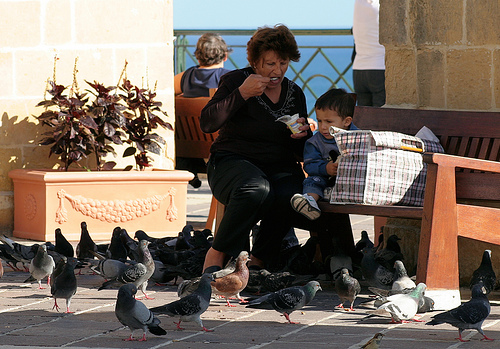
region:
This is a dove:
[425, 276, 493, 345]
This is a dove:
[366, 279, 442, 329]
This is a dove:
[205, 242, 260, 299]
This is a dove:
[235, 275, 331, 332]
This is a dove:
[325, 263, 376, 322]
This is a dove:
[156, 270, 242, 325]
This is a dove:
[110, 282, 184, 347]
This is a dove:
[40, 253, 120, 323]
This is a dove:
[96, 237, 177, 302]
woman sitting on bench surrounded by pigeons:
[17, 10, 495, 340]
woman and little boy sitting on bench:
[200, 21, 495, 296]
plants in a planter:
[15, 55, 192, 235]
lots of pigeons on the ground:
[1, 215, 486, 336]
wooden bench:
[207, 76, 492, 288]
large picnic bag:
[327, 125, 472, 202]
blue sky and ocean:
[165, 2, 352, 129]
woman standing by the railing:
[355, 0, 397, 101]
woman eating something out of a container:
[200, 28, 300, 268]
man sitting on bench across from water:
[175, 28, 247, 163]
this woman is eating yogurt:
[211, 6, 336, 251]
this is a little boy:
[277, 67, 387, 239]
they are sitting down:
[200, 16, 485, 286]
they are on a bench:
[203, 21, 458, 269]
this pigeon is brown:
[200, 239, 272, 301]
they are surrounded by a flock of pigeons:
[0, 209, 498, 343]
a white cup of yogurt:
[268, 97, 318, 167]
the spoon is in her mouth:
[258, 67, 295, 95]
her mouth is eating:
[242, 18, 312, 108]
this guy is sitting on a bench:
[172, 18, 228, 143]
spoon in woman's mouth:
[262, 75, 277, 81]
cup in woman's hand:
[279, 107, 300, 138]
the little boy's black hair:
[318, 91, 354, 111]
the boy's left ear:
[343, 115, 353, 129]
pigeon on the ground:
[112, 272, 168, 335]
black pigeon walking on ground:
[440, 277, 498, 346]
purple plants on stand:
[37, 92, 167, 165]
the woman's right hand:
[240, 69, 263, 96]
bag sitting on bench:
[336, 125, 446, 205]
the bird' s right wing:
[277, 291, 300, 307]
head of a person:
[242, 25, 302, 88]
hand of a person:
[240, 68, 274, 93]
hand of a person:
[282, 105, 312, 140]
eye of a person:
[263, 51, 278, 66]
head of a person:
[300, 79, 370, 141]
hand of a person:
[323, 156, 350, 177]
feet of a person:
[288, 185, 329, 222]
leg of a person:
[203, 191, 265, 256]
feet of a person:
[195, 254, 240, 279]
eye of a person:
[279, 56, 287, 73]